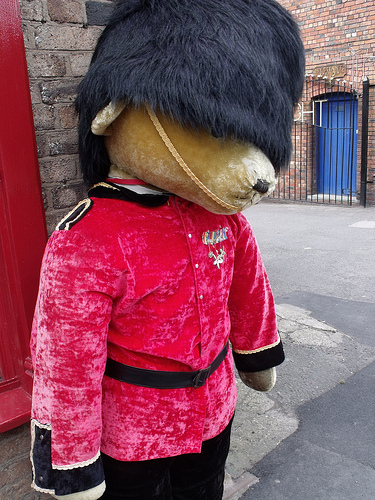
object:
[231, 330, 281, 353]
trim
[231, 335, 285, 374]
cuff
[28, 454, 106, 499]
cuff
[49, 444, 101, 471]
trim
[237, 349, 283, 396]
paws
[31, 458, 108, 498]
paws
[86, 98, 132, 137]
ear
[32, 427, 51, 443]
snap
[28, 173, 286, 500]
uniform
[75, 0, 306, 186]
hat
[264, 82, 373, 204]
fence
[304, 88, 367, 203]
door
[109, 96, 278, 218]
face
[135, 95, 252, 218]
strap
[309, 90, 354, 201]
ground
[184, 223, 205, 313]
metal buttons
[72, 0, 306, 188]
hood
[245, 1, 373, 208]
wall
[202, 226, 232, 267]
medal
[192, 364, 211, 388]
plastic clasp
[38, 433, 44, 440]
button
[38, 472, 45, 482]
button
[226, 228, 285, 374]
sleeve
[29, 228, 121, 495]
sleeve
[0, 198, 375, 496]
pavement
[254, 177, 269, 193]
nose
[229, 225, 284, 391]
arm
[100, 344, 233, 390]
belt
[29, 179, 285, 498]
jacket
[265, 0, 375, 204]
bars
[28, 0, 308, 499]
bear